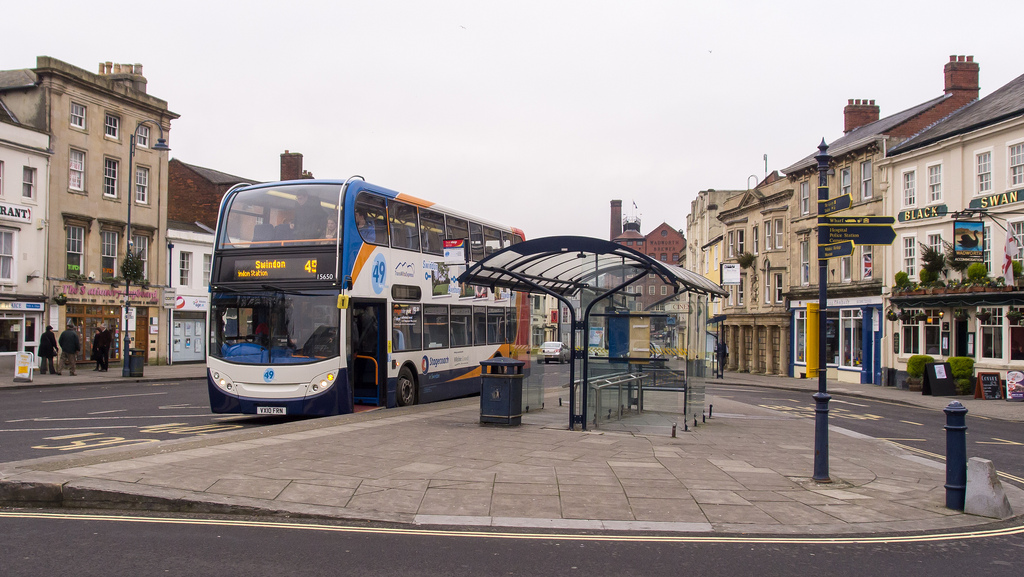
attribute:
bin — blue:
[457, 322, 542, 463]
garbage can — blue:
[480, 360, 526, 428]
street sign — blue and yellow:
[810, 182, 899, 262]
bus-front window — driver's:
[212, 282, 340, 360]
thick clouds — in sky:
[464, 59, 575, 139]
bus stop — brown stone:
[119, 411, 867, 533]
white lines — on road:
[63, 389, 167, 405]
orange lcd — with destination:
[225, 249, 331, 278]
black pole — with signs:
[795, 135, 897, 483]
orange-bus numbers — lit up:
[294, 251, 327, 278]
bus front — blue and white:
[201, 175, 355, 420]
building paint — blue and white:
[784, 292, 890, 385]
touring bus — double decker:
[203, 173, 536, 428]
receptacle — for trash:
[476, 348, 529, 431]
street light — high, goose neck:
[116, 115, 168, 375]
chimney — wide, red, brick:
[842, 98, 886, 131]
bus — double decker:
[211, 186, 534, 428]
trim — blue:
[854, 303, 889, 399]